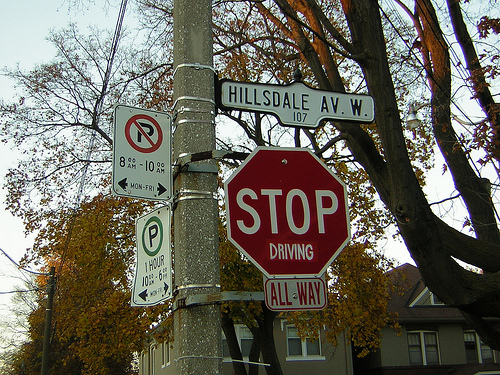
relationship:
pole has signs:
[165, 5, 229, 375] [106, 75, 376, 313]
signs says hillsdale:
[111, 79, 375, 311] [229, 82, 313, 112]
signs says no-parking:
[111, 79, 375, 311] [122, 112, 163, 155]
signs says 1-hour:
[111, 79, 375, 311] [142, 252, 167, 277]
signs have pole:
[106, 75, 376, 313] [171, 5, 224, 375]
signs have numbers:
[106, 75, 376, 313] [118, 155, 168, 173]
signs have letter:
[106, 75, 376, 313] [235, 188, 338, 234]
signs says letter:
[111, 79, 375, 311] [235, 188, 338, 234]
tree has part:
[30, 189, 170, 375] [68, 312, 124, 358]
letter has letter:
[259, 185, 285, 238] [235, 188, 338, 234]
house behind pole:
[355, 263, 497, 369] [171, 5, 224, 375]